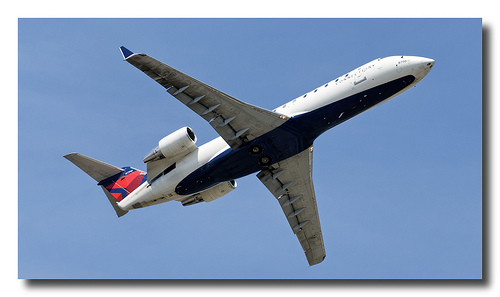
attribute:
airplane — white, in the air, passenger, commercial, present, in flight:
[63, 45, 436, 265]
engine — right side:
[143, 126, 197, 163]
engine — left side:
[182, 178, 237, 208]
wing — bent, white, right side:
[119, 45, 274, 147]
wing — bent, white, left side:
[256, 145, 326, 266]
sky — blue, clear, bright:
[19, 18, 483, 280]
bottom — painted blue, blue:
[174, 73, 415, 196]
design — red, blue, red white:
[98, 168, 147, 200]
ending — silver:
[181, 193, 204, 207]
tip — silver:
[143, 145, 164, 164]